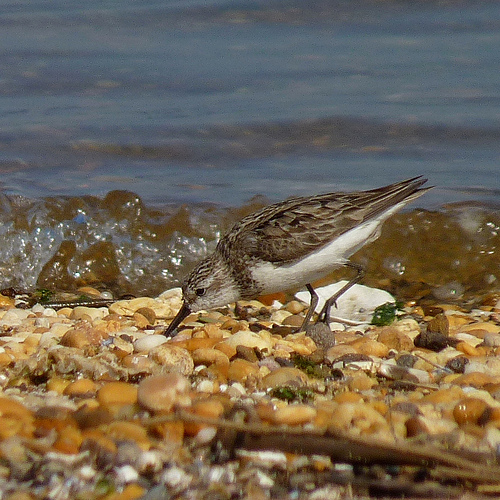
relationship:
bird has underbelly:
[160, 174, 432, 331] [261, 211, 375, 294]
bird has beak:
[160, 174, 432, 331] [162, 302, 195, 339]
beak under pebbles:
[162, 302, 195, 339] [1, 284, 495, 497]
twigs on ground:
[213, 411, 485, 495] [9, 275, 498, 496]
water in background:
[3, 3, 497, 302] [3, 9, 500, 318]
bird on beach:
[160, 174, 432, 331] [6, 19, 493, 480]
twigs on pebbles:
[213, 411, 485, 495] [1, 284, 495, 497]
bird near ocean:
[160, 174, 432, 331] [3, 3, 497, 302]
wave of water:
[6, 182, 500, 304] [3, 3, 497, 302]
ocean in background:
[3, 3, 497, 302] [3, 9, 500, 318]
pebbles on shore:
[1, 284, 495, 497] [6, 19, 493, 480]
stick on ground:
[230, 413, 499, 469] [9, 275, 498, 496]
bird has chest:
[160, 174, 432, 331] [261, 211, 375, 294]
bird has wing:
[160, 174, 432, 331] [243, 200, 376, 257]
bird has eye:
[160, 174, 432, 331] [191, 282, 208, 299]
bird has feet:
[160, 174, 432, 331] [290, 257, 368, 324]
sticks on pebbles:
[213, 411, 485, 495] [1, 284, 495, 497]